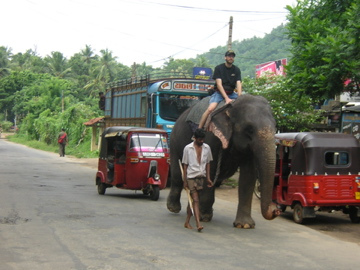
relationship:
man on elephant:
[197, 41, 266, 114] [177, 109, 333, 207]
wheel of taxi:
[140, 184, 163, 202] [104, 116, 187, 191]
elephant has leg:
[177, 109, 333, 207] [233, 177, 261, 236]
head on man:
[210, 45, 232, 63] [197, 41, 266, 114]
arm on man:
[211, 71, 237, 97] [197, 41, 266, 114]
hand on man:
[223, 94, 241, 107] [197, 41, 266, 114]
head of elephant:
[244, 91, 289, 167] [177, 109, 333, 207]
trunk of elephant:
[238, 145, 313, 222] [177, 109, 333, 207]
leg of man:
[233, 177, 261, 236] [197, 41, 266, 114]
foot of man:
[226, 212, 271, 238] [197, 41, 266, 114]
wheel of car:
[140, 184, 163, 202] [85, 138, 210, 233]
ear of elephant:
[211, 104, 250, 154] [177, 109, 333, 207]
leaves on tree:
[302, 34, 345, 77] [301, 4, 343, 85]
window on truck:
[317, 148, 348, 169] [286, 109, 334, 213]